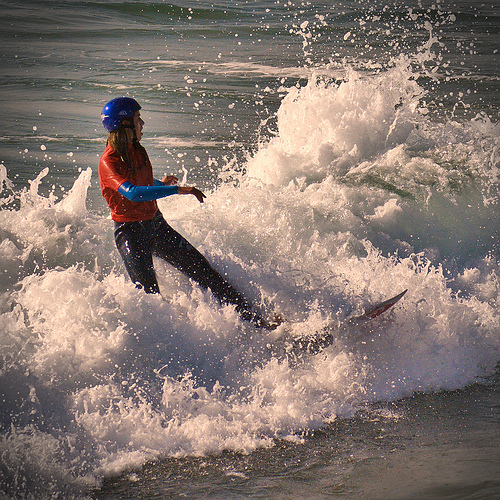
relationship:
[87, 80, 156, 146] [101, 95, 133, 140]
blue safety helmet on top of head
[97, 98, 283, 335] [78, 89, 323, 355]
person wearing wetsuit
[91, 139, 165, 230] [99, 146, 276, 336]
red shirt worn over wetsuit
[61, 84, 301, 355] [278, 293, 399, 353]
woman standing standing on surfboard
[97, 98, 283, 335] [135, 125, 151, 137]
person with mouth open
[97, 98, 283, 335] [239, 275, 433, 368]
person on surfboard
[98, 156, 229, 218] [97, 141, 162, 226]
blue underneath underneath red shirt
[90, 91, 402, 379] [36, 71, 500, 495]
person surfing surfing in ocean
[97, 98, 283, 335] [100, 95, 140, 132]
person wearing blue safety helmet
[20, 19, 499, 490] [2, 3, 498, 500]
white and gray in green ocean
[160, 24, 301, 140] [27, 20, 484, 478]
gray waves in ocean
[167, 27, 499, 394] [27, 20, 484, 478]
white and gray waves in ocean